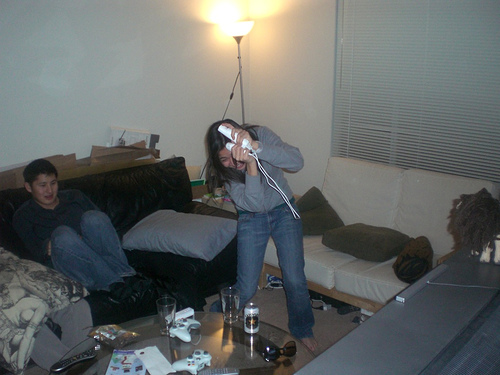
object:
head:
[221, 122, 253, 147]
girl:
[198, 119, 318, 352]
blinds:
[331, 0, 499, 185]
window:
[332, 0, 499, 186]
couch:
[0, 151, 249, 375]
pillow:
[319, 220, 411, 263]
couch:
[252, 154, 500, 332]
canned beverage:
[242, 301, 261, 334]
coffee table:
[74, 285, 356, 375]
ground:
[0, 273, 366, 375]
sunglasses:
[257, 340, 297, 361]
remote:
[45, 344, 101, 375]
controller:
[168, 347, 213, 373]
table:
[11, 310, 295, 375]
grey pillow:
[122, 208, 237, 262]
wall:
[0, 0, 338, 212]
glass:
[218, 285, 241, 325]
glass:
[155, 295, 177, 336]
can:
[243, 302, 259, 334]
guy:
[13, 156, 153, 306]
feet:
[103, 274, 168, 324]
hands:
[229, 145, 256, 165]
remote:
[216, 123, 252, 155]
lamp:
[203, 0, 256, 43]